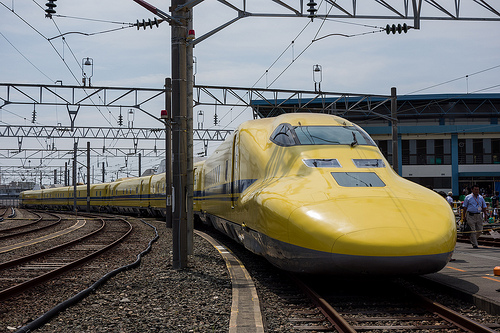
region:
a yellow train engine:
[194, 111, 453, 271]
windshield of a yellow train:
[270, 123, 376, 147]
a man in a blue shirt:
[463, 185, 487, 249]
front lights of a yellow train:
[306, 157, 387, 168]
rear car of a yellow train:
[20, 189, 43, 208]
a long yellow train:
[18, 112, 453, 279]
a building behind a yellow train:
[252, 100, 499, 245]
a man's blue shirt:
[463, 192, 487, 214]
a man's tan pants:
[465, 211, 486, 249]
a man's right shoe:
[471, 240, 480, 249]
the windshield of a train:
[266, 117, 376, 154]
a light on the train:
[301, 152, 342, 173]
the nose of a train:
[301, 196, 488, 283]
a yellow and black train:
[11, 97, 470, 300]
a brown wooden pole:
[161, 2, 200, 282]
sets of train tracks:
[0, 201, 498, 331]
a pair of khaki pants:
[464, 211, 489, 243]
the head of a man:
[467, 182, 484, 199]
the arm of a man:
[456, 194, 473, 222]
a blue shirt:
[460, 189, 490, 215]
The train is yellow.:
[15, 80, 462, 284]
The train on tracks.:
[15, 95, 465, 331]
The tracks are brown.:
[5, 207, 490, 331]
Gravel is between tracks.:
[2, 202, 489, 329]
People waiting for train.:
[430, 176, 498, 246]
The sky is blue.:
[1, 0, 492, 171]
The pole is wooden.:
[150, 2, 200, 263]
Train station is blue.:
[236, 76, 496, 222]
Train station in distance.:
[247, 67, 497, 198]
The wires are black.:
[2, 2, 335, 182]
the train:
[234, 62, 396, 327]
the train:
[50, 91, 456, 327]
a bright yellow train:
[6, 112, 468, 289]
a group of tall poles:
[163, 0, 197, 271]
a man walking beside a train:
[462, 185, 492, 253]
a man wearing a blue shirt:
[456, 177, 496, 251]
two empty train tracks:
[3, 211, 153, 322]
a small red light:
[154, 107, 169, 118]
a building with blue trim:
[254, 85, 499, 192]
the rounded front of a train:
[242, 189, 476, 289]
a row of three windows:
[399, 137, 448, 172]